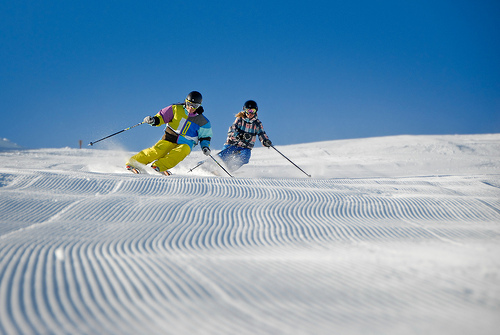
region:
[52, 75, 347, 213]
two people skiing down a slope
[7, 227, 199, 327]
row of thin lines in the snow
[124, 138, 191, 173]
bright yellow snow pants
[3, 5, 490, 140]
dark blue sky with no clouds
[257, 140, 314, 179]
ski pole stuck in the snow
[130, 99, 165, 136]
hand around the top of the ski pole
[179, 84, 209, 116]
hat and goggles are on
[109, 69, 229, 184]
person leaning to one side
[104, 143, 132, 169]
snow coming off the skis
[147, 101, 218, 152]
multicolored jacket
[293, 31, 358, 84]
blue sky above the snow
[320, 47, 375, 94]
sky with no clouds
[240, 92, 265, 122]
helmet on the person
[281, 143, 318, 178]
ski pole in person's hand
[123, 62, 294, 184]
two people skiing together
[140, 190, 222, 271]
tracks in the snow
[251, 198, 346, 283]
snow on the ground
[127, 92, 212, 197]
man wearing different colors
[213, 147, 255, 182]
snow in the air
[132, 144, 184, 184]
yellow pants on man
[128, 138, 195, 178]
THE SKIER IS WEARING YELLOW PANTS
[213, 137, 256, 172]
THE SKIER IS WEARING BLUE PANTS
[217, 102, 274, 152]
THE SKIER IS WEARING A PLAID JACKET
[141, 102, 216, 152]
THE SKIER IS WEARING A BLUE YELLOW AND PINK JACKET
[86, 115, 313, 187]
THE SKIERS HAVE POLES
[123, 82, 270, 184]
THE SKIERS ARE LEANING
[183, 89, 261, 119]
THE SKIERS ARE WEARING HELMETS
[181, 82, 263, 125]
THE HELMETS ARE BLACK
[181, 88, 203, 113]
THIS IS A HELMET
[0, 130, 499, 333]
THE SNOW IS WHITE AND POWDERY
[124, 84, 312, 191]
two skiers on slope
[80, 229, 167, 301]
smooth lines in snow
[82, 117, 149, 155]
pole in skier hand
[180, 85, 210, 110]
helmet on skier head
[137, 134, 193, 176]
yellow pants on skier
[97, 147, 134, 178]
snow kicked up by skies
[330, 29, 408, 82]
blue of daytime sky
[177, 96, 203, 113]
goggles on skiers face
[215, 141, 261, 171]
blue pants on skier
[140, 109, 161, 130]
glove on skier's hand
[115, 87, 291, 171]
this is a man and a woman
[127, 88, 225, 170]
the man is snow skating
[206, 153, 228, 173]
this is a stick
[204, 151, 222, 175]
the stick is thin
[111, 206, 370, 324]
the place is full of snow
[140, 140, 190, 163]
the legs are slanted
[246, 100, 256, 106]
she is wearing helmet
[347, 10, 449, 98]
the sky is blue in color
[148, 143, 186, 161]
the trousers are yellow in color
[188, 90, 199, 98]
the helmet is black in color